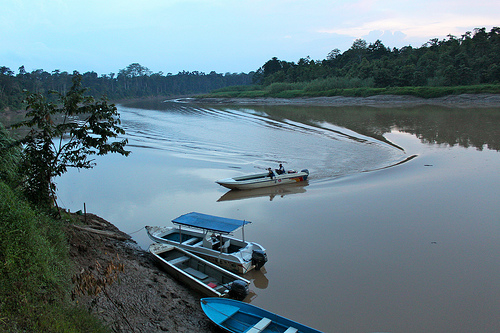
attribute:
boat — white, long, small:
[215, 161, 310, 192]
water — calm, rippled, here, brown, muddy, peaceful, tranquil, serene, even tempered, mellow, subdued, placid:
[48, 99, 499, 331]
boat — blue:
[141, 220, 272, 277]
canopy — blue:
[173, 210, 251, 245]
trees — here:
[2, 20, 499, 170]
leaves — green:
[2, 26, 496, 187]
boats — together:
[134, 213, 315, 332]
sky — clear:
[0, 1, 495, 70]